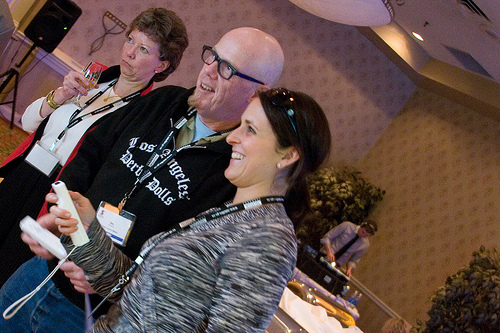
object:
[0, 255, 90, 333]
jeans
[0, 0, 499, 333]
event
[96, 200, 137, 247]
badges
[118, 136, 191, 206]
writing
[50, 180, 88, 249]
wii mote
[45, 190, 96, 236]
hand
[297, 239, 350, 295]
dj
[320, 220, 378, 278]
man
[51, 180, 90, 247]
controllers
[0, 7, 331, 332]
they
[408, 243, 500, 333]
bushes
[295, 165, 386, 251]
bushes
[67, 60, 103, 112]
wine glass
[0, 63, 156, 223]
shirt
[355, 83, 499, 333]
wallpaper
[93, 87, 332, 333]
woman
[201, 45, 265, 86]
black glasses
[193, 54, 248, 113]
face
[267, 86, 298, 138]
sunglasses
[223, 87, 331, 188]
head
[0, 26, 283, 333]
man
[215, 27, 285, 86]
bald head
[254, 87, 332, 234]
hair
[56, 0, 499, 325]
walls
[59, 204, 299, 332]
shirt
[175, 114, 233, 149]
shirt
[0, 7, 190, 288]
woman